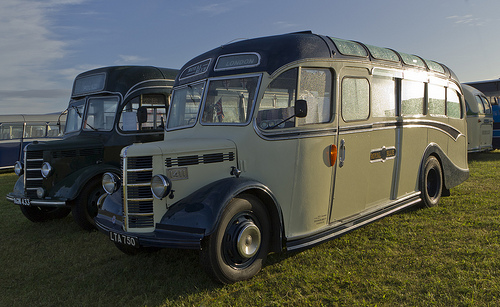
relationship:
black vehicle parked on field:
[6, 65, 330, 232] [300, 235, 498, 294]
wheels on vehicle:
[192, 152, 459, 274] [137, 60, 463, 240]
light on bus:
[329, 142, 340, 166] [93, 30, 469, 285]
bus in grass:
[90, 34, 480, 277] [2, 152, 499, 305]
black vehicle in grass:
[6, 65, 330, 232] [2, 152, 499, 305]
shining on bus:
[357, 60, 454, 127] [142, 35, 496, 241]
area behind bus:
[3, 117, 59, 141] [0, 93, 92, 216]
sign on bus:
[179, 52, 262, 81] [90, 34, 480, 277]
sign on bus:
[71, 72, 107, 98] [90, 34, 480, 277]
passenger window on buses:
[297, 67, 464, 126] [19, 39, 481, 279]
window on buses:
[165, 72, 263, 131] [19, 39, 481, 279]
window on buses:
[139, 94, 165, 125] [19, 39, 481, 279]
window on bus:
[165, 72, 263, 131] [90, 34, 480, 277]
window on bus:
[165, 72, 263, 131] [8, 49, 175, 221]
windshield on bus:
[61, 94, 120, 130] [458, 77, 495, 161]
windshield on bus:
[61, 94, 120, 130] [2, 113, 62, 179]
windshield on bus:
[64, 96, 120, 135] [10, 59, 167, 222]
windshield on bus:
[64, 96, 120, 135] [42, 50, 166, 232]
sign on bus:
[179, 52, 262, 81] [89, 47, 465, 251]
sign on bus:
[175, 59, 211, 77] [90, 34, 480, 277]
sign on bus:
[67, 71, 108, 96] [8, 49, 175, 221]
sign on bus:
[179, 52, 262, 81] [8, 49, 175, 221]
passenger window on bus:
[297, 67, 464, 126] [90, 34, 480, 277]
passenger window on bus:
[301, 66, 333, 124] [90, 34, 480, 277]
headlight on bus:
[102, 172, 121, 195] [93, 30, 469, 285]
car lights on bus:
[151, 174, 172, 199] [93, 30, 469, 285]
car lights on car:
[151, 174, 172, 199] [10, 42, 243, 240]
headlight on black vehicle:
[99, 160, 219, 197] [6, 65, 330, 232]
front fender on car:
[3, 192, 68, 206] [5, 65, 181, 232]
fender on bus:
[163, 183, 297, 246] [93, 30, 469, 285]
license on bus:
[104, 229, 147, 249] [93, 30, 469, 285]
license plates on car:
[14, 198, 30, 205] [15, 70, 215, 229]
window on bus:
[198, 72, 260, 126] [93, 30, 469, 285]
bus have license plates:
[93, 30, 469, 285] [109, 221, 132, 251]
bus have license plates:
[93, 30, 469, 285] [17, 190, 36, 210]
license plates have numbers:
[14, 198, 30, 205] [118, 235, 138, 245]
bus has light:
[93, 30, 469, 285] [333, 143, 338, 164]